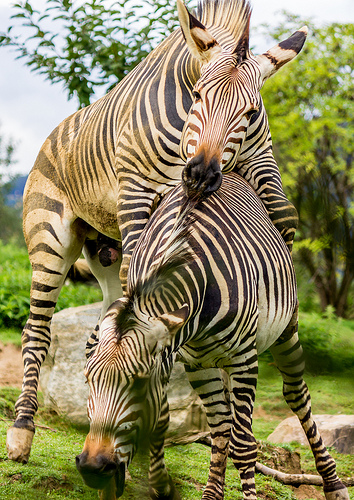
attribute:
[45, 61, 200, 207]
stripes — black, white 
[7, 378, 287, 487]
grass — Green 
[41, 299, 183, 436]
rock — large 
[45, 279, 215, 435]
rock — large 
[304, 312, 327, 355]
leaves — green 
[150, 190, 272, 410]
stripes — green , white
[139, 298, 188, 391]
fur — black 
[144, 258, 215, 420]
ear — black , white